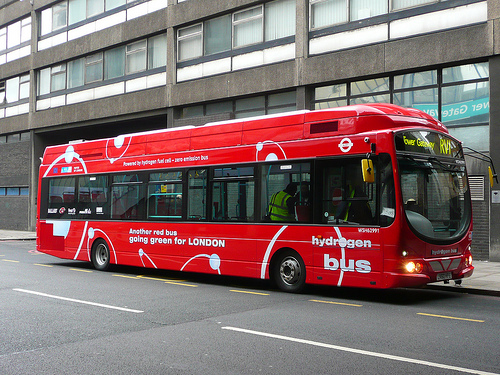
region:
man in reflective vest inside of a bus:
[263, 183, 300, 225]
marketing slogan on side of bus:
[124, 225, 226, 252]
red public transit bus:
[37, 103, 476, 288]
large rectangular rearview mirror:
[359, 144, 379, 190]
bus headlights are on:
[395, 252, 473, 278]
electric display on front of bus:
[395, 132, 466, 154]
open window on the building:
[0, 79, 8, 103]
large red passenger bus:
[33, 102, 476, 294]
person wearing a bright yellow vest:
[268, 180, 299, 220]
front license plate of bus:
[433, 272, 454, 281]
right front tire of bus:
[270, 248, 307, 292]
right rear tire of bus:
[90, 238, 110, 271]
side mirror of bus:
[359, 155, 376, 185]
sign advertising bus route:
[395, 129, 456, 156]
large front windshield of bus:
[392, 124, 474, 246]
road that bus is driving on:
[3, 234, 495, 372]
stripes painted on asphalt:
[0, 252, 495, 368]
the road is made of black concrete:
[3, 239, 495, 373]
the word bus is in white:
[321, 251, 373, 273]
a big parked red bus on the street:
[32, 102, 475, 297]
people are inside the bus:
[261, 178, 380, 226]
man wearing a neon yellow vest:
[268, 189, 295, 221]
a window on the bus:
[111, 173, 143, 218]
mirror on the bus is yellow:
[359, 155, 376, 185]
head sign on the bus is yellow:
[401, 131, 458, 157]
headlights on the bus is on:
[399, 254, 477, 274]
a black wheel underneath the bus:
[267, 248, 309, 289]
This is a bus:
[19, 92, 489, 312]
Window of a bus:
[41, 171, 79, 218]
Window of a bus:
[73, 171, 109, 217]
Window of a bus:
[111, 172, 141, 221]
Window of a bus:
[146, 166, 185, 224]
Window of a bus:
[178, 167, 208, 224]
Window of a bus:
[209, 166, 258, 227]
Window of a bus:
[257, 159, 312, 224]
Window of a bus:
[313, 150, 381, 233]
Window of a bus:
[391, 150, 471, 252]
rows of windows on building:
[2, 1, 497, 229]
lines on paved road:
[0, 258, 498, 373]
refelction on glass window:
[314, 61, 490, 129]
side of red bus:
[35, 105, 470, 290]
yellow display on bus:
[401, 130, 462, 152]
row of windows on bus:
[39, 153, 394, 225]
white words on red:
[129, 228, 373, 274]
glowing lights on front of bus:
[403, 254, 474, 273]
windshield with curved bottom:
[400, 163, 470, 245]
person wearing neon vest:
[269, 182, 299, 222]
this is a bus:
[17, 108, 487, 313]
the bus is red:
[20, 112, 475, 303]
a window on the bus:
[43, 170, 85, 220]